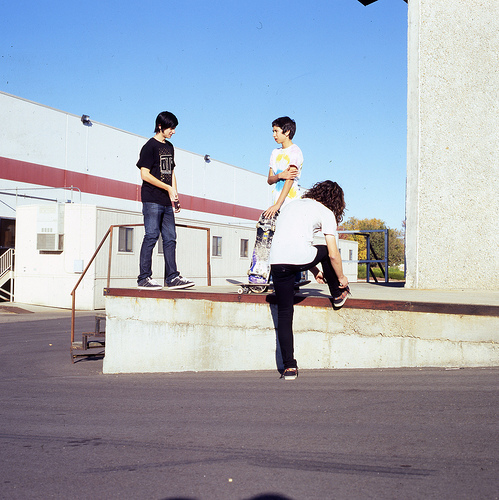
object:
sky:
[0, 0, 52, 92]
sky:
[63, 15, 125, 111]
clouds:
[347, 149, 403, 210]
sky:
[163, 35, 367, 103]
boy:
[261, 116, 304, 221]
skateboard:
[235, 210, 280, 295]